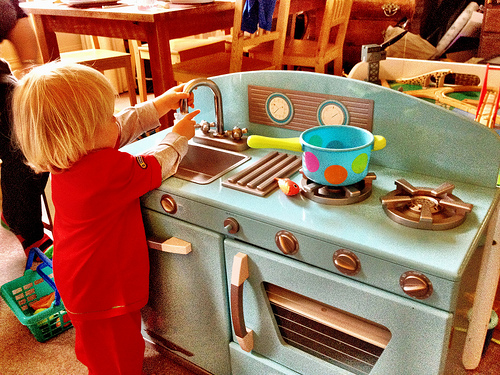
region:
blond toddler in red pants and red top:
[13, 57, 200, 373]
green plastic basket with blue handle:
[2, 244, 70, 344]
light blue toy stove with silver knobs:
[131, 68, 499, 374]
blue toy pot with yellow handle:
[247, 111, 386, 183]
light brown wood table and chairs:
[14, 0, 356, 101]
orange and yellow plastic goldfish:
[273, 177, 300, 197]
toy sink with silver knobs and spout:
[154, 77, 252, 187]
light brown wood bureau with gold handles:
[304, 2, 421, 56]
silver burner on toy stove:
[380, 171, 472, 231]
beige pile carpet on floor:
[2, 324, 75, 373]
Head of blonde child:
[13, 57, 128, 165]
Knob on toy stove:
[331, 249, 360, 279]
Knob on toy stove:
[401, 270, 431, 299]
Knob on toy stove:
[271, 231, 299, 258]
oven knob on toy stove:
[218, 215, 240, 237]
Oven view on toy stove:
[258, 290, 402, 373]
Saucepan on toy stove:
[247, 125, 387, 185]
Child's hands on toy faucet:
[162, 77, 229, 137]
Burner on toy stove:
[378, 172, 475, 239]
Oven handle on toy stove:
[230, 249, 258, 356]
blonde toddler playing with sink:
[6, 58, 201, 373]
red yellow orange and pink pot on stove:
[238, 121, 381, 191]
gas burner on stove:
[377, 176, 477, 235]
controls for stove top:
[392, 268, 440, 302]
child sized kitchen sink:
[142, 75, 255, 196]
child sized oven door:
[215, 231, 455, 373]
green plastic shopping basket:
[2, 235, 78, 347]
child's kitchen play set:
[91, 63, 498, 374]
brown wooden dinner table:
[16, 3, 248, 110]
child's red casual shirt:
[41, 147, 172, 318]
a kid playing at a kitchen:
[14, 21, 482, 356]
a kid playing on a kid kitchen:
[24, 32, 489, 358]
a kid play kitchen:
[40, 27, 467, 372]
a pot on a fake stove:
[254, 90, 493, 318]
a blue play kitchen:
[140, 50, 493, 374]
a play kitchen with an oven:
[119, 107, 497, 372]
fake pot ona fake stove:
[175, 90, 494, 230]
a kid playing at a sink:
[16, 43, 307, 220]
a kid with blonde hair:
[4, 25, 159, 212]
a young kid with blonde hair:
[19, 34, 229, 342]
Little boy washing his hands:
[10, 61, 201, 374]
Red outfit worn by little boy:
[50, 147, 164, 374]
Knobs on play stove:
[156, 192, 434, 302]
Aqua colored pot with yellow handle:
[242, 124, 376, 185]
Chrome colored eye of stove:
[381, 177, 476, 233]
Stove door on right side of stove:
[218, 235, 455, 372]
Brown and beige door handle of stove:
[228, 249, 259, 354]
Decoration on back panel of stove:
[245, 83, 374, 134]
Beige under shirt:
[145, 131, 187, 181]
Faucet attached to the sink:
[176, 76, 223, 141]